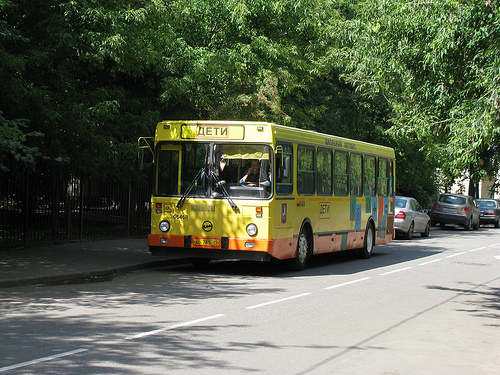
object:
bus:
[136, 119, 397, 271]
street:
[1, 225, 499, 374]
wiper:
[210, 171, 239, 212]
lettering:
[197, 127, 227, 137]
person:
[240, 160, 271, 187]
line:
[0, 313, 225, 374]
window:
[317, 148, 333, 195]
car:
[393, 195, 431, 240]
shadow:
[0, 314, 388, 374]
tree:
[41, 0, 157, 161]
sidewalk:
[0, 235, 179, 286]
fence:
[0, 169, 151, 250]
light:
[245, 222, 258, 236]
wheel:
[286, 230, 310, 272]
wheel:
[364, 222, 375, 259]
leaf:
[114, 100, 120, 107]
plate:
[193, 238, 220, 246]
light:
[394, 210, 406, 219]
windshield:
[212, 145, 273, 200]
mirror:
[282, 157, 291, 180]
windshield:
[395, 199, 406, 208]